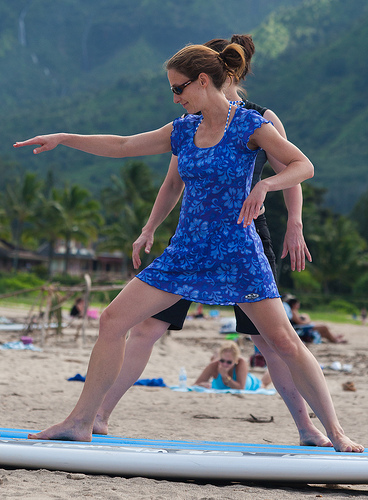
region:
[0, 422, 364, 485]
Two surfboards on the sand.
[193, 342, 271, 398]
Woman laying on the sand.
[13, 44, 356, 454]
Woman in blue dress on surfboard.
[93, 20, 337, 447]
Woman in black shorts on surfboard.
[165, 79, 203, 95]
Sunglasses on the woman.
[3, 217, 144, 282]
House in the background.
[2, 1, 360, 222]
Mountains in the background.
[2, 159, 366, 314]
Palm trees in the background.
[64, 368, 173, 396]
Blue towel laying in the sand.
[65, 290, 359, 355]
People in the background.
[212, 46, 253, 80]
pony tail on woman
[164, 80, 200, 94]
sun glasses on woman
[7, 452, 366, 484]
white surfboard on beach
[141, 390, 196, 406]
sand on the beach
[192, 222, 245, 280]
part of blue dress on woman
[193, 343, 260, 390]
woman relaxing on beach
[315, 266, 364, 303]
greenery next to beach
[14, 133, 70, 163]
the ladies fingers and hand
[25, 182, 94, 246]
the palm trees by beach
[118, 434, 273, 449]
a portion of blue surfboard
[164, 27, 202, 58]
hair of a lady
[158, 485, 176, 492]
part of a sand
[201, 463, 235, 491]
part of a pipe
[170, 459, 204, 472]
edge of a pipe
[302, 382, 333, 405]
part of a leg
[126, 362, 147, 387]
part of a leg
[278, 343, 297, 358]
part of a knee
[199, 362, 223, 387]
part of a hand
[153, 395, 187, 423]
part of some sand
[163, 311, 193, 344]
edge of a short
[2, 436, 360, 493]
the white surf board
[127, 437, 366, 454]
the blue surf board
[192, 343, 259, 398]
woman in the back ground lying down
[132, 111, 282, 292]
woman's floral blue dress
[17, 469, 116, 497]
sand in front of the white surf board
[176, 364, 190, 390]
water bottle in the back ground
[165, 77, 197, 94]
woman's dark sunglasses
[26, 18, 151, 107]
mountain in the background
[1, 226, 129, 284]
building in the background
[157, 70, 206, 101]
sunglasses on a head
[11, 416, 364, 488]
a surfboard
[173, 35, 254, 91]
hair in a bun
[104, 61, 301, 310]
a woman wearing a blue dress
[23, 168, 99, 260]
palm trees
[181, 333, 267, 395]
a woman laying on a towel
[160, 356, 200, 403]
a water bottle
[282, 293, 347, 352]
a person sitting in a chair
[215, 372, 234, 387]
a watch on a wrist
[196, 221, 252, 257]
flowers on a dress